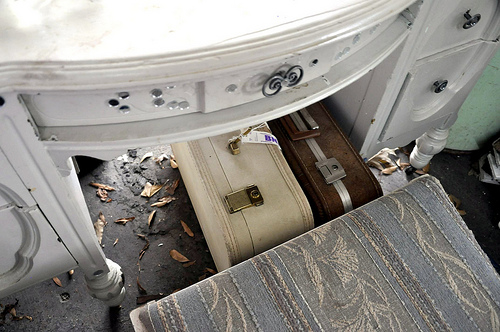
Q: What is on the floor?
A: Suitcases.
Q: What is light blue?
A: A chair seat.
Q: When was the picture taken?
A: Daytime.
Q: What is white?
A: The dresser.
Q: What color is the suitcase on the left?
A: White.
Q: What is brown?
A: Suitcase on the right.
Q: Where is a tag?
A: On white suitcase.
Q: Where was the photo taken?
A: In a room.